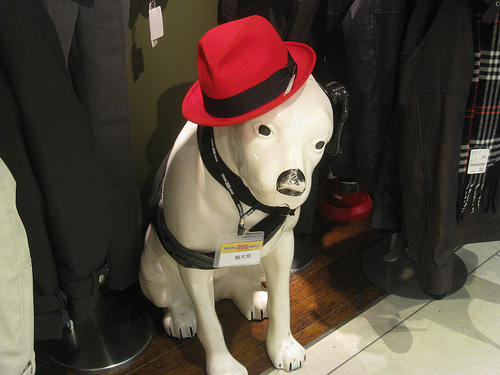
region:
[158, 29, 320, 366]
this is a dog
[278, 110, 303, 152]
the dog is white in color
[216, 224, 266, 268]
this is a berg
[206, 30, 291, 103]
this is a hat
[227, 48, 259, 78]
the hat is red in color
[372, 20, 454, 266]
this is a coat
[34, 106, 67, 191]
the coat is black in color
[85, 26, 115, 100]
this is a trouser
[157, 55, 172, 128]
this is a wall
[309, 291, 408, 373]
this is the ground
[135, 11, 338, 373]
A ceramic sculpture of a dog wearing a hat.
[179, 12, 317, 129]
A very classy looking red hat.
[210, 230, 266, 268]
A name tag around the neck of the dog.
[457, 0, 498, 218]
A brand new red black and white scarf.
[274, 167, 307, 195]
The worn out nose of a ceramic dog.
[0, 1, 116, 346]
A black coat hanged inside a store.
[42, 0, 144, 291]
A gray pair of pants hanged inside of a store.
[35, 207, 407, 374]
The wooden floor is under all the items.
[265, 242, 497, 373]
The white ceramic tile is in front of the dog.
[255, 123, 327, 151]
The two black eyes of a ceramic dog sculpture.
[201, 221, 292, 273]
hanging dog tag with name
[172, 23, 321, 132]
red and black hat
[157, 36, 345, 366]
fake standing dog figurine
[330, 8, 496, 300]
black hanging jacket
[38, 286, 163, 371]
stand for hanging jackets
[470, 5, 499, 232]
red black and white scarf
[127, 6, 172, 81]
shadow of hanging tag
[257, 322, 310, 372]
paw of mannequin dog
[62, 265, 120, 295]
cuff link of jacket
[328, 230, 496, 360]
shadow of hanging jacket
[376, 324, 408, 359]
part of a shade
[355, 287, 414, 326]
part of a shade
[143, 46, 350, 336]
this is a dogs doll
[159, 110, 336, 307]
the dog is white in color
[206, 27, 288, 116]
the dog is wearing a cap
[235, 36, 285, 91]
the hat is red in color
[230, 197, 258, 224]
this is a ribbon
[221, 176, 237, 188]
the ribbon is black in color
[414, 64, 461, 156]
this is a jacket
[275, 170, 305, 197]
the nose is black in color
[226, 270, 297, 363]
the legs are short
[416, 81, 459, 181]
the jacket is black in color